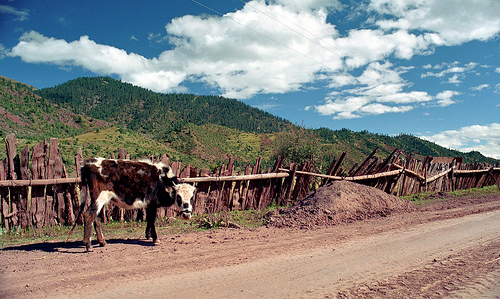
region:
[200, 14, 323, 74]
The clouds are white and fluffy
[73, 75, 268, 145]
The grass is the color green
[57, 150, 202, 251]
The cow on the road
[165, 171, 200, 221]
The head of the cow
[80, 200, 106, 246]
The back legs of the cow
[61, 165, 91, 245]
The tail of the cow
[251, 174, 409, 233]
The pile of dirt on the ground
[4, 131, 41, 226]
brown wooden fence board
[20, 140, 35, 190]
brown wooden fence board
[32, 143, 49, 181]
brown wooden fence board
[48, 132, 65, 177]
brown wooden fence board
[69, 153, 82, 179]
brown wooden fence board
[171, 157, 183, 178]
brown wooden fence board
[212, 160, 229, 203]
brown wooden fence board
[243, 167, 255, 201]
brown wooden fence board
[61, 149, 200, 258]
brown and white cow on road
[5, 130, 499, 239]
broken wooden fence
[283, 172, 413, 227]
dirt mound on road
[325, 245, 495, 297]
tracks in dirt road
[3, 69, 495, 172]
grass covered mountains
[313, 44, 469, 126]
white clouds in blue sky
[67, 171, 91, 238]
cow tail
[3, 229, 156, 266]
dark shadow on dirt road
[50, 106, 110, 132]
dirt ground on grass mountain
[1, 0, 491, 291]
Scene in a countryside.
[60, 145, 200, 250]
Cow on the side of a clay road.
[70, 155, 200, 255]
Cow with white and brown coat.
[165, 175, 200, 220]
Cow looking at the photographer.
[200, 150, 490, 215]
Leaning uneven fence along the road.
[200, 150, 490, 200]
Fence is made of wood.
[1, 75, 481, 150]
High mountains covered with green trees.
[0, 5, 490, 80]
Blue sky with white and grey clouds.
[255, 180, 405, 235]
Big bump on the road side.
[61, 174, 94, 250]
Cow with long brown tail.